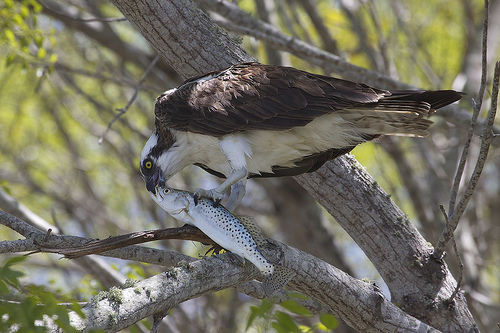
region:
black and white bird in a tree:
[118, 58, 466, 200]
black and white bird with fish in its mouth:
[132, 58, 467, 198]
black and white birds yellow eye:
[141, 158, 154, 172]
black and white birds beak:
[142, 168, 167, 195]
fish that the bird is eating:
[149, 181, 297, 303]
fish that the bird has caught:
[144, 167, 297, 303]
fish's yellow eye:
[160, 187, 175, 197]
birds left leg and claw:
[188, 167, 244, 212]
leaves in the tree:
[1, 259, 83, 331]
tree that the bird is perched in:
[1, 2, 497, 332]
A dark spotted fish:
[136, 175, 299, 295]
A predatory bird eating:
[138, 60, 465, 214]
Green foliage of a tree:
[0, 260, 85, 332]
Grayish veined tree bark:
[331, 172, 429, 242]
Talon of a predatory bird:
[190, 180, 227, 207]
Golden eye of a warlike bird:
[142, 158, 152, 170]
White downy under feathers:
[247, 134, 294, 158]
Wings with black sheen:
[155, 60, 389, 131]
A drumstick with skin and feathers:
[185, 68, 255, 169]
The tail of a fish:
[259, 263, 299, 300]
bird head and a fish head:
[131, 141, 196, 228]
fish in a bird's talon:
[149, 161, 301, 304]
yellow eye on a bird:
[138, 156, 158, 171]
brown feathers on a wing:
[202, 92, 237, 113]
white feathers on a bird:
[235, 136, 275, 170]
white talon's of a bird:
[181, 173, 247, 221]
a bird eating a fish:
[116, 49, 473, 314]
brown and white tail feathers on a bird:
[367, 90, 442, 147]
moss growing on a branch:
[40, 261, 197, 318]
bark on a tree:
[157, 11, 212, 62]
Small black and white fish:
[140, 177, 302, 302]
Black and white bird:
[120, 58, 467, 215]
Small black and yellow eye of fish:
[162, 186, 172, 194]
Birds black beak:
[140, 169, 177, 197]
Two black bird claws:
[188, 188, 235, 214]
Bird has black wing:
[150, 58, 394, 148]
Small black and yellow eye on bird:
[142, 158, 152, 170]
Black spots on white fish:
[188, 186, 283, 274]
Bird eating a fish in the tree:
[112, 54, 481, 320]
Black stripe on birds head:
[147, 124, 182, 159]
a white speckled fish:
[146, 182, 295, 295]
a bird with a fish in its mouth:
[138, 60, 464, 203]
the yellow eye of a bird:
[142, 156, 155, 171]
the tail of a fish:
[252, 256, 298, 305]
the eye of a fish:
[164, 187, 170, 194]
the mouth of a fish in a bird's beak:
[147, 170, 167, 203]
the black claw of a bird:
[190, 190, 197, 202]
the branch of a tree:
[0, 237, 440, 327]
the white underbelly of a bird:
[180, 108, 345, 165]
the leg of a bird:
[190, 166, 249, 207]